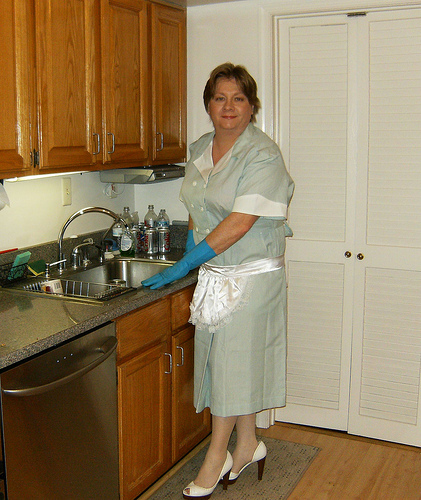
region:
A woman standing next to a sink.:
[13, 60, 294, 497]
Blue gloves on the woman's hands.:
[139, 224, 215, 289]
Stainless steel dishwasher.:
[0, 315, 120, 494]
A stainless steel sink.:
[3, 248, 182, 301]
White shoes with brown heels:
[176, 436, 269, 497]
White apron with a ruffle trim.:
[183, 258, 285, 328]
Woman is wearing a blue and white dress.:
[182, 120, 294, 416]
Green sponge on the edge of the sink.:
[2, 250, 30, 276]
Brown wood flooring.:
[134, 421, 417, 496]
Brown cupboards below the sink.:
[117, 283, 219, 498]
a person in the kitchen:
[6, 60, 294, 497]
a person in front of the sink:
[44, 61, 306, 498]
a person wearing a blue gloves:
[142, 61, 292, 328]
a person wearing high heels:
[145, 62, 308, 498]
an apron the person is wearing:
[188, 257, 291, 332]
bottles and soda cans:
[118, 203, 171, 255]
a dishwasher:
[1, 320, 120, 498]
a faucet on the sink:
[44, 206, 132, 276]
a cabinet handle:
[91, 131, 101, 155]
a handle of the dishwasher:
[0, 338, 119, 398]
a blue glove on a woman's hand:
[140, 234, 218, 291]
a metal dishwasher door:
[5, 319, 119, 499]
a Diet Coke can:
[157, 226, 173, 256]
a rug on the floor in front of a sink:
[145, 418, 323, 498]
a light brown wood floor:
[134, 427, 419, 498]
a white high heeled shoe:
[181, 447, 232, 497]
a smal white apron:
[184, 249, 289, 331]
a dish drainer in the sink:
[23, 277, 126, 300]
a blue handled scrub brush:
[99, 237, 121, 257]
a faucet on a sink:
[55, 206, 127, 272]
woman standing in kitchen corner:
[16, 28, 340, 492]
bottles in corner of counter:
[108, 194, 165, 258]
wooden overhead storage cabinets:
[5, 2, 182, 177]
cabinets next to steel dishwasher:
[1, 287, 203, 493]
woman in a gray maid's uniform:
[179, 61, 293, 491]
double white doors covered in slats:
[270, 2, 414, 443]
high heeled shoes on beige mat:
[163, 431, 316, 494]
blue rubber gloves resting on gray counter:
[127, 219, 218, 304]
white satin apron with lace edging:
[184, 250, 284, 329]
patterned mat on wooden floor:
[145, 407, 414, 493]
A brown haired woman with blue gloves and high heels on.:
[140, 63, 294, 497]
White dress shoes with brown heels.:
[181, 439, 265, 498]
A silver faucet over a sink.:
[56, 204, 131, 276]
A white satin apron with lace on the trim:
[187, 254, 286, 330]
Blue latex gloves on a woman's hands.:
[140, 229, 216, 292]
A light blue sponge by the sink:
[7, 251, 31, 278]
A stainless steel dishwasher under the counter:
[4, 320, 120, 498]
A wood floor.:
[244, 422, 419, 497]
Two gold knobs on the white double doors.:
[342, 250, 364, 259]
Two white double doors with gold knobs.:
[271, 12, 419, 448]